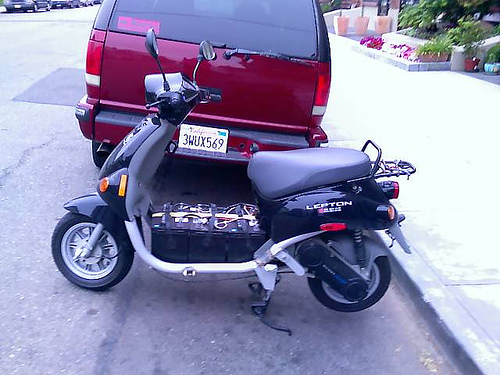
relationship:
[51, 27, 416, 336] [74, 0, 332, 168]
moped behind car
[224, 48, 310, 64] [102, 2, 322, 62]
windshield wiper on rear window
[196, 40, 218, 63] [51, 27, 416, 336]
mirror on side of moped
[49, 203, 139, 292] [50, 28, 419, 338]
tire on front of moped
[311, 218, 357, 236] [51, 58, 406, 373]
reflector on moped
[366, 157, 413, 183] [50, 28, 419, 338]
rack on moped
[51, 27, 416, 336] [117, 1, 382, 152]
moped parked behind car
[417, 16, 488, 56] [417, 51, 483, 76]
plants are in pots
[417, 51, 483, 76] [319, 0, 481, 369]
pots are alongside sidewalk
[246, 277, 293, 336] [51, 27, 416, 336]
kickstand on moped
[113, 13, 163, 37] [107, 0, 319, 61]
sticker on rear window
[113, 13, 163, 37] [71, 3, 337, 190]
sticker on back of car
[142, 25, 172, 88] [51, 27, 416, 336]
mirror attached to moped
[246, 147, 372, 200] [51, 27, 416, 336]
seat on moped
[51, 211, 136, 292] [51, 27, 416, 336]
tire on moped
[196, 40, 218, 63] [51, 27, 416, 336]
mirror on moped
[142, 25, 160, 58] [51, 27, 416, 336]
mirror on moped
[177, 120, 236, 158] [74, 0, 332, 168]
license on car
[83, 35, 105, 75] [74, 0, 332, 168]
light on car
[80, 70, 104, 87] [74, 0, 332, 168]
light on car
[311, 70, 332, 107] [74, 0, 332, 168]
light on car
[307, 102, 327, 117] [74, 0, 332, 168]
light on car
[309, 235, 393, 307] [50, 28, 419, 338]
rear wheel on moped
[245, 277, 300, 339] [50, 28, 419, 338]
kickstand on moped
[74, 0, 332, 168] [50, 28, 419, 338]
car in front moped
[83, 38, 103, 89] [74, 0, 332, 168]
rear light on car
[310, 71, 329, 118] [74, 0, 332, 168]
rear light on car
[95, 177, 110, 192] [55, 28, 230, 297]
light on moped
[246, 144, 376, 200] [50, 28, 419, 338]
seat on moped